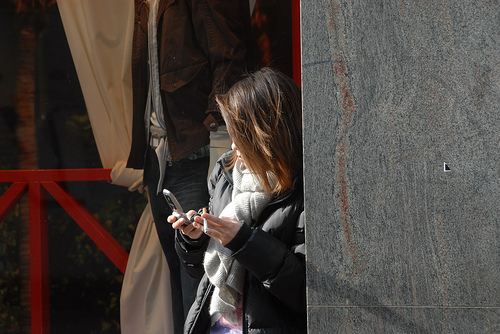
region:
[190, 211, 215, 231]
cigarette in left hand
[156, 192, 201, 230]
cell phone in right hand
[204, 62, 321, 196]
brown hair on woman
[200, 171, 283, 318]
white scarf on woman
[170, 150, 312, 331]
black coat on woman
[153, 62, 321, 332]
woman is texting in cold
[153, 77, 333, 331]
woman is smoking in cold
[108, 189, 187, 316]
white cloth around red bar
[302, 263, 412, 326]
shadow of woman on wall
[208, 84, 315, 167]
light and dark brown hair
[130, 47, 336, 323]
A woman looks at her phone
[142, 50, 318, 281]
A woman smoking a cigarette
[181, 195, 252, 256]
A woman's hand holding a cigarette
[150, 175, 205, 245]
A mobile phone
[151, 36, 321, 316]
A woman wearing a scarf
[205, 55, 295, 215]
A brunette woman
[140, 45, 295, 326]
A woman wearing a coat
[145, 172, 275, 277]
Human hands holding objects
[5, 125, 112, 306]
A red painted railing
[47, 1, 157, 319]
A curtain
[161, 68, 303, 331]
woman holding cell phone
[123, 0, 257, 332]
person wearing brown jacket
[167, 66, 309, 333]
woman wearing black jacket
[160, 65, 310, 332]
woman wearing white scarf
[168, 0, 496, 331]
woman next to gray wall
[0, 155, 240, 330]
red fence behind woman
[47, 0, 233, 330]
white curtain behind person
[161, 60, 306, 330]
woman with brown hair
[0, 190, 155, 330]
green bushes behind red fence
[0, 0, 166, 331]
white curtain next to red fence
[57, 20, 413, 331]
a women with short hair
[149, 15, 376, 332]
a woman smoking a cigerrate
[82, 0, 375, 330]
a women holding a cell phone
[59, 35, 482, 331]
a woman holding a phone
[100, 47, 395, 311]
a woman wearing jacket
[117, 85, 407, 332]
a woman wearing a scarf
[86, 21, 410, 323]
a woman leaning against the wall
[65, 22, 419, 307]
a woman that is outside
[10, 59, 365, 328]
a woman looking at her phone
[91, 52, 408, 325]
a woman looking at her cell phone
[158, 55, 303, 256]
Woman is looking at her cell phone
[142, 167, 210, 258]
The cell phone is a flip phone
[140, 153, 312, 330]
Woman is wearing a bubble coat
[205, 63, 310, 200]
Woman has brown hair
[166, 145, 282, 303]
Woman is wearing a scarf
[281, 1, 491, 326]
Woman is by a concrete wall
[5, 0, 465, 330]
Photo was taken in the daytime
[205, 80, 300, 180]
A side view of a woman's head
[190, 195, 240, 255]
Woman is smoking outside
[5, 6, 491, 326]
Photo was taken outdoors